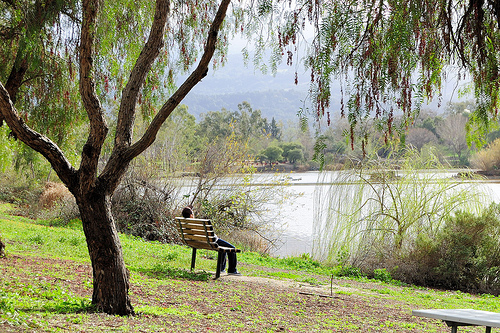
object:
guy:
[181, 206, 240, 277]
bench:
[175, 217, 242, 280]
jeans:
[214, 238, 237, 272]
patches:
[261, 290, 281, 303]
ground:
[0, 208, 498, 333]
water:
[320, 167, 479, 276]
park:
[1, 2, 495, 331]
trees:
[257, 0, 499, 226]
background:
[0, 123, 497, 330]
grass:
[0, 203, 500, 333]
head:
[182, 207, 194, 218]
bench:
[410, 308, 499, 332]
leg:
[216, 250, 223, 278]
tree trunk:
[78, 187, 143, 319]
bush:
[35, 183, 76, 223]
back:
[175, 217, 216, 248]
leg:
[191, 249, 200, 270]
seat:
[186, 245, 243, 252]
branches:
[306, 1, 339, 122]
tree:
[0, 0, 249, 315]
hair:
[185, 208, 191, 214]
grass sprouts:
[211, 289, 223, 297]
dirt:
[255, 274, 291, 288]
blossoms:
[387, 109, 396, 130]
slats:
[177, 229, 211, 236]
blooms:
[419, 33, 437, 65]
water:
[128, 165, 499, 260]